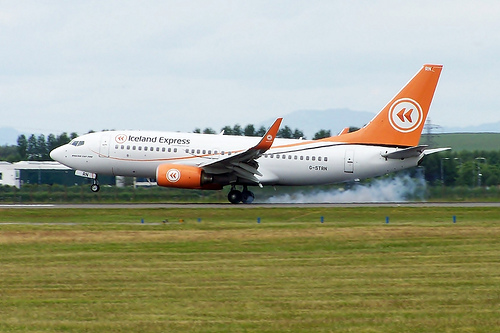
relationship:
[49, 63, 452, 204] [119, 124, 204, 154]
airport has lettering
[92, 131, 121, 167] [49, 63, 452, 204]
door on airport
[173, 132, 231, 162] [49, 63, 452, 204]
window of airport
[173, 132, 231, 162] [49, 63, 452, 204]
window on airport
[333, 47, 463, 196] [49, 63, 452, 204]
tail of airport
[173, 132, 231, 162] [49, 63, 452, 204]
window at airport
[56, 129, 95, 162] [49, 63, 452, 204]
windshield on airport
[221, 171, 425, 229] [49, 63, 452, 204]
smoke under airport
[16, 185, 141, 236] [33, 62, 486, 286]
runway at airport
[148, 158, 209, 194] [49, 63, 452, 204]
engine of airport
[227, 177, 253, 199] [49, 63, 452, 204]
wheel of airport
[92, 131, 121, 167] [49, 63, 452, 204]
door of airport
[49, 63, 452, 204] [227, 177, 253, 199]
airport has wheel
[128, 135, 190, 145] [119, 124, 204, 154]
logo of airline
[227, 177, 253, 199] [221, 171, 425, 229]
tire has smoke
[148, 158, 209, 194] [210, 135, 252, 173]
engine on wing